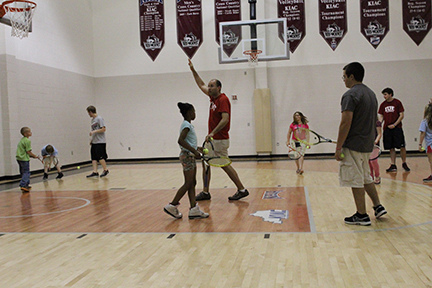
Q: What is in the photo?
A: People.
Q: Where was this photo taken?
A: In the gymnasium.